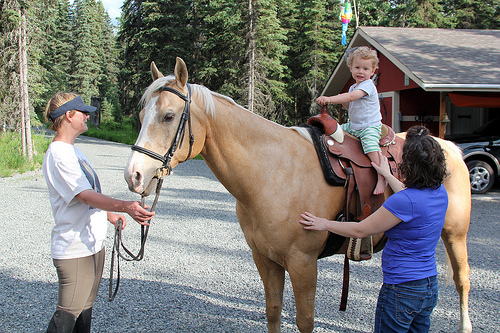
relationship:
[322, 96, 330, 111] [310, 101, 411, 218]
horn attached to saddle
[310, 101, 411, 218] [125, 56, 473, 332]
saddle on top of horse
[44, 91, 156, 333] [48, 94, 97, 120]
woman wearing visor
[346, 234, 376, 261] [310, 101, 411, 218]
stirrups connected to saddle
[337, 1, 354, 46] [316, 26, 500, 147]
windsock hanging from building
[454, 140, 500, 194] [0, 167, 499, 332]
car parked in parking lot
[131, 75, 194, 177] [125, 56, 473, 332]
bridle placed on horse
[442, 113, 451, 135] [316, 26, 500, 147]
dinner bell attached to building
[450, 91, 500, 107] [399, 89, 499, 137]
awning over front porch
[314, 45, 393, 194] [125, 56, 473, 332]
child riding horse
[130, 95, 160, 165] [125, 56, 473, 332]
design on horse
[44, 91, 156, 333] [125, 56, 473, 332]
woman leading horse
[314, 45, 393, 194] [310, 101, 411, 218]
child sitting on saddle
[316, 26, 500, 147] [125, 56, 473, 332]
building behind horse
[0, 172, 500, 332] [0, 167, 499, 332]
gravel on surface of parking lot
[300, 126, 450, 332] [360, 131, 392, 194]
mom holding leg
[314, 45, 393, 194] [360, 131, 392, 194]
child has leg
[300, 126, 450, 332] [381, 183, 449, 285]
mom wearing shirt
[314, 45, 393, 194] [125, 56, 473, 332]
child sitting on horse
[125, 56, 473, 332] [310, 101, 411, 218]
horse wearing saddle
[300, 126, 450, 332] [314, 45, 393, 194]
mom looking at child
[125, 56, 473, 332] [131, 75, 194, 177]
horse wearing bridle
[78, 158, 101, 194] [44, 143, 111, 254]
picture printed on shirt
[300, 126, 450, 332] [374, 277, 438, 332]
mom wearing jeans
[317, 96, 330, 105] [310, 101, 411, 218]
hand on top of saddle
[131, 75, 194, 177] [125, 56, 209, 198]
bridle on top of head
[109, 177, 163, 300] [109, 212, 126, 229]
reins in hand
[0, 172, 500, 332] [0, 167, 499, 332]
gravel on top of parking lot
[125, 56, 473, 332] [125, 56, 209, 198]
horse has head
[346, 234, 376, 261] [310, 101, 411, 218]
stirrups attached to saddle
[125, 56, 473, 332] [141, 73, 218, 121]
horse has mane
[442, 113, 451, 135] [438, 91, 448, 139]
dinner bell attached to column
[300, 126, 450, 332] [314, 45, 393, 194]
mom holding child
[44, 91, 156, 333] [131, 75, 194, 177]
woman holding bridle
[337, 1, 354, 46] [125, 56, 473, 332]
windsock behind horse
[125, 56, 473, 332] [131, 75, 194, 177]
horse has bridle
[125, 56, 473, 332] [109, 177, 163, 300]
horse has reins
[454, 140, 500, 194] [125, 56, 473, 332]
car behind horse